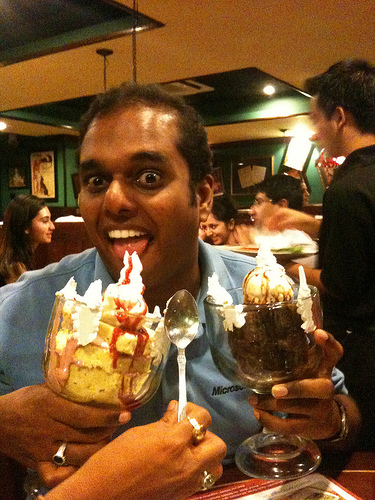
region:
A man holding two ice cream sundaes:
[7, 51, 371, 498]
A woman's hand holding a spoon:
[70, 284, 233, 499]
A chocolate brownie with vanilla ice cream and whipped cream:
[186, 249, 334, 424]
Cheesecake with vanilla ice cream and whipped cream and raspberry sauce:
[15, 249, 177, 429]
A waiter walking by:
[300, 41, 372, 384]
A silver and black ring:
[44, 440, 73, 468]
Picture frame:
[17, 143, 65, 203]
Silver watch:
[328, 390, 362, 455]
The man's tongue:
[102, 236, 152, 269]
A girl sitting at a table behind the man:
[0, 180, 60, 273]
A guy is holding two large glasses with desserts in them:
[20, 80, 347, 423]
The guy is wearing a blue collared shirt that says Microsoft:
[71, 117, 264, 427]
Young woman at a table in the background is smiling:
[202, 179, 268, 245]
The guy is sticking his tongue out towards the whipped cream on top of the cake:
[38, 116, 212, 398]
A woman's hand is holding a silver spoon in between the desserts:
[43, 285, 244, 498]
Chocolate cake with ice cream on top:
[202, 245, 331, 390]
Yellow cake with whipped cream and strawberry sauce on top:
[39, 248, 173, 404]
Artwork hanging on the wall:
[210, 125, 327, 197]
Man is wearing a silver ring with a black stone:
[8, 379, 85, 474]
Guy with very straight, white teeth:
[55, 74, 223, 288]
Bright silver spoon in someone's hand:
[155, 288, 209, 416]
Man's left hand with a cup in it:
[228, 328, 363, 451]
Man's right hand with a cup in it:
[0, 388, 138, 478]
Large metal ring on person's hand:
[183, 414, 214, 446]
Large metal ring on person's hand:
[194, 468, 222, 492]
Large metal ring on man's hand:
[41, 438, 80, 468]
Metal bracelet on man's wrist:
[328, 398, 355, 447]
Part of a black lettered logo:
[205, 376, 252, 403]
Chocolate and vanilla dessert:
[199, 245, 332, 390]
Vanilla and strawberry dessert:
[40, 248, 170, 409]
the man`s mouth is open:
[63, 213, 166, 261]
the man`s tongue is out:
[86, 233, 158, 265]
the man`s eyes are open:
[60, 153, 177, 201]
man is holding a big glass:
[199, 243, 351, 438]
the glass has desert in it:
[190, 231, 339, 405]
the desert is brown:
[209, 292, 317, 387]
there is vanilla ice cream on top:
[220, 244, 292, 298]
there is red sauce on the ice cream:
[94, 246, 150, 406]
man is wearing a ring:
[23, 430, 83, 464]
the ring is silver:
[29, 431, 73, 471]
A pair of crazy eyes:
[80, 159, 168, 193]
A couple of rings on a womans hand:
[79, 395, 226, 498]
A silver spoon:
[163, 283, 202, 435]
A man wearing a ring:
[2, 382, 129, 488]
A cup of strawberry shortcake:
[38, 246, 177, 417]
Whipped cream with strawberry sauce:
[106, 246, 149, 316]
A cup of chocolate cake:
[201, 237, 338, 475]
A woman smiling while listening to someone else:
[196, 184, 248, 250]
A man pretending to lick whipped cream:
[13, 74, 341, 456]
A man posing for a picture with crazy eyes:
[7, 88, 348, 416]